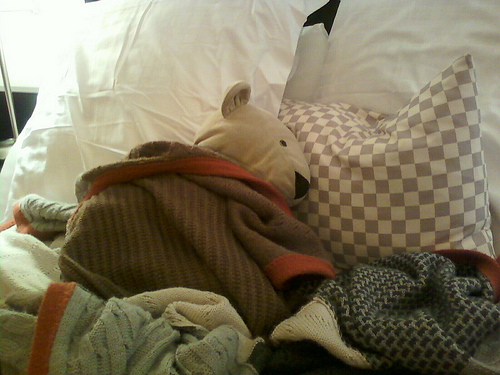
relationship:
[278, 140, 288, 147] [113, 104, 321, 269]
black eye of a teddy bear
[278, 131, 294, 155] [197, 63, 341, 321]
black eye of a teddy bear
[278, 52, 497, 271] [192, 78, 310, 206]
pillow has bear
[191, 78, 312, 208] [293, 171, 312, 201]
bear has nose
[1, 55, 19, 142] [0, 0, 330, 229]
bar by pillow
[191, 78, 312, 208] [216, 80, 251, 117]
bear has ear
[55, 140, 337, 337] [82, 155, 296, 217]
blanket has border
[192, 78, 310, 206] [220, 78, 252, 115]
bear has ear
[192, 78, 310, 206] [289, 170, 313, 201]
bear has nose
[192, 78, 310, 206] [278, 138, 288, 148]
bear has eye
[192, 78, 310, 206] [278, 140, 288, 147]
bear has black eye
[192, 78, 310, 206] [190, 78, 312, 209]
bear has head